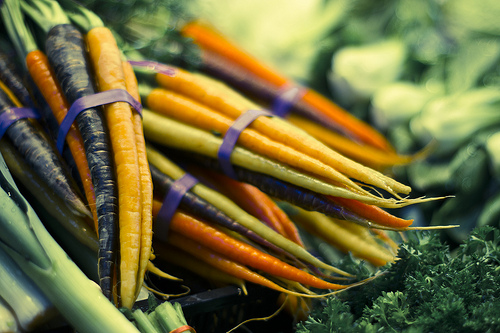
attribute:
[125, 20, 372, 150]
carror — dark colored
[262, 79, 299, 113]
band — blue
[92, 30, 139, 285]
carrot — dark colored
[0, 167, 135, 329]
vegetable stalk — green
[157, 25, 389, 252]
carrot — orange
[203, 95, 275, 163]
band — blue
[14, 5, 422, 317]
vegetables — fresh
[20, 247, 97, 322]
onions — green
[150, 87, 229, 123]
carrot — orange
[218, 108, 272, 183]
band — purple, rubber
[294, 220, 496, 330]
parsley — green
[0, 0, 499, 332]
vegetables — fresh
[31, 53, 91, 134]
carrots — colorful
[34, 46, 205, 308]
carrot — one, purple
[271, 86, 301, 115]
rubber band — red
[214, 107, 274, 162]
rubber band — red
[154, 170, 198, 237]
rubber band — red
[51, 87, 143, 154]
rubber band — red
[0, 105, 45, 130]
rubber band — red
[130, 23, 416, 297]
carrot — orange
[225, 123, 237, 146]
band. — blue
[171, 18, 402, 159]
carrot — carrot tops, out of focus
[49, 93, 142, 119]
band — blue